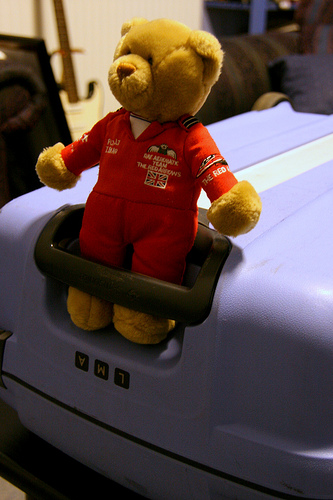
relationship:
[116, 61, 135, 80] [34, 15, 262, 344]
nose on bear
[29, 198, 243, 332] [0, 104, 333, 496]
handle on luggage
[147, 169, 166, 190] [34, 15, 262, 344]
logo on bear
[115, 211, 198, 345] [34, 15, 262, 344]
leg on bear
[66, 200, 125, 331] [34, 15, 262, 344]
leg on bear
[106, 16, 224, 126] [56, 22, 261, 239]
head on bear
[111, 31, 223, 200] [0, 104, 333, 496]
teddybear on luggage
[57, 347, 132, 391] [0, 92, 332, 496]
letters on luggage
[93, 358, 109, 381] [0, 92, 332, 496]
letter on luggage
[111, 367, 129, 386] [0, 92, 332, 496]
letter on luggage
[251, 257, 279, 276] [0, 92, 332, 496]
scratch on luggage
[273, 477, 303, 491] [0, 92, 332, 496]
mark on luggage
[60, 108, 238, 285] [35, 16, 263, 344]
aviation suit on doll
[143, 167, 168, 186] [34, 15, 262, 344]
flag on bear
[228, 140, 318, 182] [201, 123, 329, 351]
stripe on suitcase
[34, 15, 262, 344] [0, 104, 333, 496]
bear in luggage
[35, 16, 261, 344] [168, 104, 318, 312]
bear in luggage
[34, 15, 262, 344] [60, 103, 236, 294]
bear in suit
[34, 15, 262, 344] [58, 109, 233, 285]
bear in suit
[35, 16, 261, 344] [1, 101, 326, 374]
bear in luggage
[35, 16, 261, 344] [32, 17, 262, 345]
bear wearing aviation suit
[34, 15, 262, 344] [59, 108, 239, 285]
bear wearing aviation suit